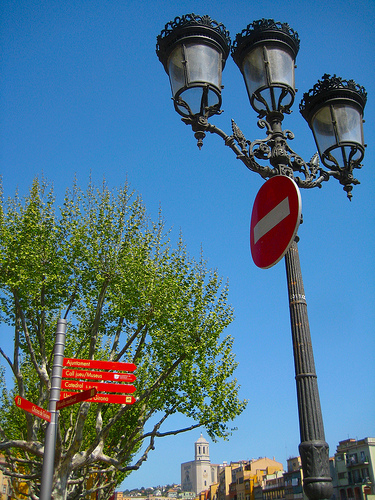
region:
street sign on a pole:
[235, 173, 312, 276]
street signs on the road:
[56, 347, 144, 416]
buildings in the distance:
[180, 439, 301, 497]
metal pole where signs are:
[46, 309, 65, 498]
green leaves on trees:
[157, 269, 217, 398]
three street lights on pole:
[147, 3, 371, 184]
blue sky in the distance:
[321, 269, 361, 415]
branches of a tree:
[144, 421, 183, 443]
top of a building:
[193, 430, 211, 461]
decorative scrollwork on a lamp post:
[226, 114, 331, 190]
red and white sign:
[236, 156, 304, 274]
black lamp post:
[155, 10, 230, 113]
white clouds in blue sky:
[13, 23, 74, 74]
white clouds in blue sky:
[63, 14, 99, 72]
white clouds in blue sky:
[315, 258, 356, 308]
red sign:
[58, 355, 146, 419]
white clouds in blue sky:
[40, 89, 87, 142]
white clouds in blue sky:
[115, 56, 128, 88]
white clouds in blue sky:
[163, 192, 210, 220]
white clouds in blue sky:
[253, 366, 281, 409]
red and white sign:
[50, 355, 148, 415]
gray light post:
[160, 14, 235, 127]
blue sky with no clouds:
[20, 29, 66, 78]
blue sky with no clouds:
[38, 83, 83, 120]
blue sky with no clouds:
[108, 98, 143, 121]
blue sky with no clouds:
[250, 337, 282, 367]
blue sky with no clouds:
[306, 208, 373, 285]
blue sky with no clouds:
[316, 321, 349, 344]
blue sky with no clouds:
[256, 403, 282, 440]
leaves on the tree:
[97, 217, 180, 316]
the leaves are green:
[100, 209, 150, 279]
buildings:
[218, 459, 277, 481]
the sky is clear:
[330, 239, 373, 298]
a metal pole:
[39, 430, 60, 498]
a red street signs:
[64, 361, 135, 390]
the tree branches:
[137, 430, 163, 450]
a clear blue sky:
[150, 154, 223, 212]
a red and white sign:
[244, 173, 307, 260]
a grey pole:
[285, 263, 317, 374]